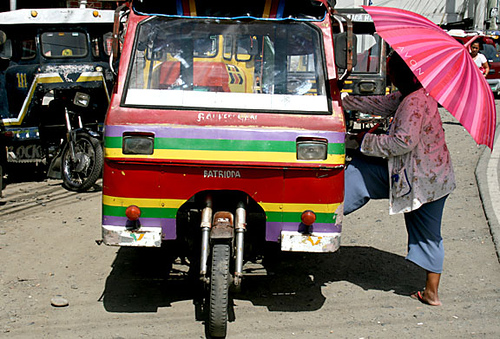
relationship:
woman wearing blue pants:
[342, 50, 445, 305] [339, 155, 446, 277]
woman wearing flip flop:
[342, 52, 455, 305] [410, 289, 444, 308]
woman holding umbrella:
[342, 50, 445, 305] [365, 4, 496, 149]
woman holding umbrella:
[342, 52, 455, 305] [365, 4, 496, 149]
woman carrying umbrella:
[342, 52, 455, 305] [367, 3, 499, 139]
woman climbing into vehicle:
[342, 52, 455, 305] [90, 0, 357, 330]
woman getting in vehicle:
[342, 52, 455, 305] [90, 0, 357, 330]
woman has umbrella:
[342, 52, 455, 305] [364, 2, 484, 157]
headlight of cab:
[120, 136, 153, 156] [115, 31, 397, 323]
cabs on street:
[0, 0, 115, 190] [17, 211, 87, 298]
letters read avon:
[394, 39, 427, 79] [388, 40, 427, 80]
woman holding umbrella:
[342, 52, 455, 305] [364, 2, 484, 157]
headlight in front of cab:
[95, 121, 189, 188] [97, 0, 350, 338]